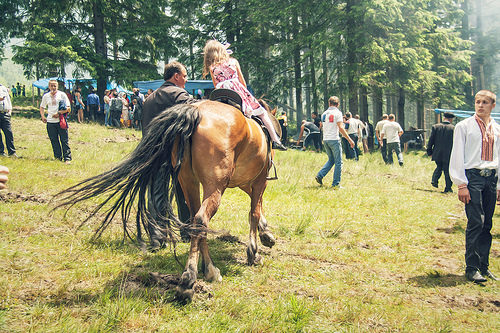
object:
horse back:
[184, 99, 267, 144]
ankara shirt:
[39, 90, 72, 123]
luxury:
[446, 113, 499, 190]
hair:
[200, 39, 231, 81]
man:
[139, 60, 202, 253]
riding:
[40, 38, 286, 306]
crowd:
[0, 37, 500, 282]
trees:
[0, 0, 183, 118]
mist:
[0, 0, 500, 160]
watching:
[71, 83, 87, 124]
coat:
[139, 78, 199, 143]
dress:
[206, 56, 266, 120]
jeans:
[314, 140, 341, 189]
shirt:
[320, 105, 343, 141]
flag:
[327, 114, 334, 124]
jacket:
[426, 121, 456, 163]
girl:
[200, 38, 291, 152]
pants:
[462, 168, 500, 276]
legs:
[244, 173, 269, 253]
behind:
[170, 105, 227, 185]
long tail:
[41, 102, 222, 255]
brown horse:
[40, 99, 276, 304]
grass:
[0, 115, 500, 332]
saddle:
[207, 88, 272, 142]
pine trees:
[344, 0, 439, 131]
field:
[0, 116, 500, 333]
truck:
[131, 80, 213, 98]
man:
[447, 88, 500, 280]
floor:
[0, 114, 500, 333]